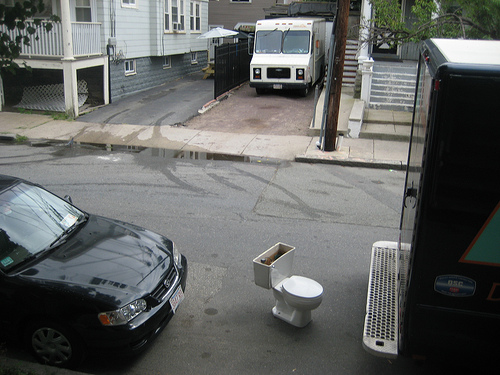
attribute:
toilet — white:
[247, 234, 322, 335]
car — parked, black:
[5, 168, 189, 360]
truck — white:
[236, 11, 330, 103]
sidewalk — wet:
[50, 112, 219, 167]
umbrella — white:
[195, 21, 238, 44]